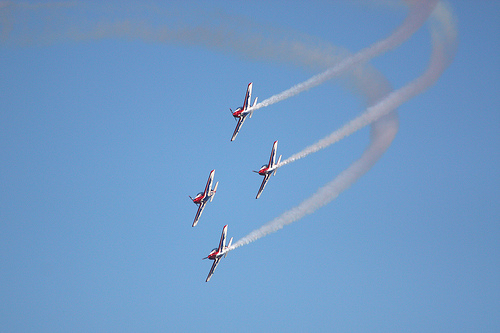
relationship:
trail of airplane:
[276, 3, 462, 158] [223, 77, 262, 144]